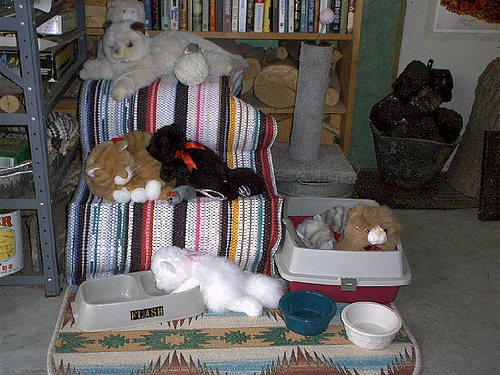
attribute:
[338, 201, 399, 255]
animal — brown, stuffed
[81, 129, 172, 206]
cat — brown, stuffed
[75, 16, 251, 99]
animal — large, white, stuffed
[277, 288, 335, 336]
water bowl — green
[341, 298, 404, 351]
water bowl — white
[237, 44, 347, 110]
firewood — cut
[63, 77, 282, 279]
blanket — multi colored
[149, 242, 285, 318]
teddy bear — white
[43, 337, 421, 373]
towel — colorful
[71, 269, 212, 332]
food dish — tan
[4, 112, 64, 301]
shelf — steel, grey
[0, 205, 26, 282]
can — red, yellow, white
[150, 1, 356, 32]
books — on a wood shelf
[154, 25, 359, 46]
shelf — wood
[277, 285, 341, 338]
bowl — blue, plastic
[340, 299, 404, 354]
bowl — white, plastic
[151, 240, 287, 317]
animal — white, furry, stuffed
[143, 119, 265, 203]
animal — black, stuffed, brown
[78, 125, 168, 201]
cat — brown, white, stuffed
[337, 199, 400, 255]
teddy bear — in litter box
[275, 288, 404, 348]
dog bowls — on Indian print rug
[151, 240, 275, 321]
white/stuffed animal — lying face down in dog dish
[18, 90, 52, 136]
corner — of metal shelf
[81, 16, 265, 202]
stuffed animals — lying on striped rug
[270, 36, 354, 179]
cat-scratching-post — gray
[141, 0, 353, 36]
books — lined on wooden shelf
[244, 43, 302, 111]
cut logs — on wooden shelf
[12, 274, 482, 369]
light/gray floor — with rug on top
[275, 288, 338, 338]
dog-food-bowl — dark blue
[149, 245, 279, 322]
fluffy/white cat — with pink ribbon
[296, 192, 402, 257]
two/stuffed cats — in a litter box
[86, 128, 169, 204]
orange cat — with white paws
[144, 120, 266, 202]
black/stuffed cat — with red bow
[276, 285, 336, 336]
cat dish — Blue, plastic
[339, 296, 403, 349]
food dish — white plastic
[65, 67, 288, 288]
striped blanket — on a chair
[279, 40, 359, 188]
grey carpet — scratching post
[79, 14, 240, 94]
stuffed animal — beige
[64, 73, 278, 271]
rug — striped, colorful